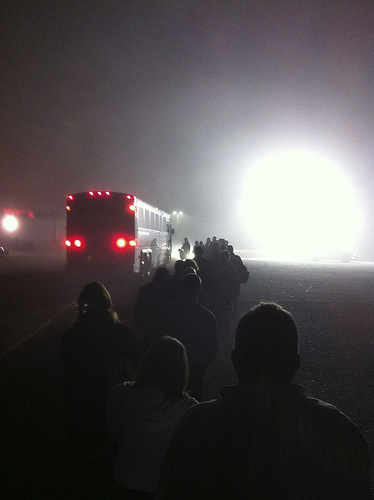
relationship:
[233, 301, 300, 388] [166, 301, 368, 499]
head of person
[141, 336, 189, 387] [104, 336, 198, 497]
head of person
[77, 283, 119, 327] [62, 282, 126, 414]
head of person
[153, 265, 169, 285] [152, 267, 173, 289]
back of head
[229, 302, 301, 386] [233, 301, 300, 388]
back of head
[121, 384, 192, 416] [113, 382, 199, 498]
hood of jacket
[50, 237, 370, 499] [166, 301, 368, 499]
group of person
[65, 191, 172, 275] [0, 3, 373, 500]
bus in dark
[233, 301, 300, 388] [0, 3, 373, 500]
head in dark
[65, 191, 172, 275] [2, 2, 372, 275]
bus in night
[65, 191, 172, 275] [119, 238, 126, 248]
bus has light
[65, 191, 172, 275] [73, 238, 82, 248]
bus has light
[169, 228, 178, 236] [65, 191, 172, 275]
mirror on bus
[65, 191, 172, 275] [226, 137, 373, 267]
bus in front of light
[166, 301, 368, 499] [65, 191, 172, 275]
person waiting to board bus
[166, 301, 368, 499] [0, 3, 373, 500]
person standing in dark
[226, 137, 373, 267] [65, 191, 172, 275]
light in front of bus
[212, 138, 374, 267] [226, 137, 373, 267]
building behind light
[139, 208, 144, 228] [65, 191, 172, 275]
window on bus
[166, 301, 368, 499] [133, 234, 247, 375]
person standing in line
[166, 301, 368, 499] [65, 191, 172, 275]
person waiting to get on bus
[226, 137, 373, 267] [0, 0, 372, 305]
light in background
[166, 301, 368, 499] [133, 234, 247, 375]
person waiting in line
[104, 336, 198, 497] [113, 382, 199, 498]
person wearing jacket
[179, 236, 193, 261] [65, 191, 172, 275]
person loading up on bus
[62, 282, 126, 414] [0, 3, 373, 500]
person in dark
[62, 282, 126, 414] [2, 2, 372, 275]
person at night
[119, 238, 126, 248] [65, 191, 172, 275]
light on bus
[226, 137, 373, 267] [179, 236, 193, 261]
light shining on person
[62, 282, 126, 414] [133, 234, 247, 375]
person in line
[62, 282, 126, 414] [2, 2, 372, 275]
person traveling at night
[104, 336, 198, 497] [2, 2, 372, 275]
person traveling at night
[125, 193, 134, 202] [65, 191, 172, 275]
light on bus